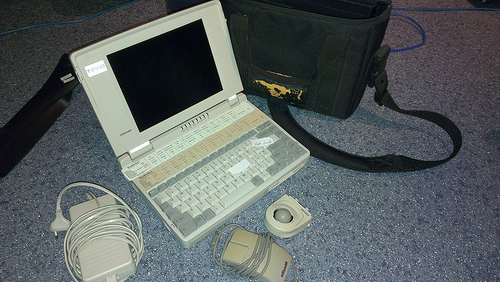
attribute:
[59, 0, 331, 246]
laptop — gray, opened, old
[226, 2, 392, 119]
bag — nylon, black, worn, cloth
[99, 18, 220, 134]
screen — black, blank, dark, empty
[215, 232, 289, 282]
mouse — wrapped, gray, plastic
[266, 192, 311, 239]
trackball — gray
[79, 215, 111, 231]
cord — wrapped, gray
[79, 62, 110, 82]
label — white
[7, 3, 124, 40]
wire — blue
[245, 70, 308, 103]
patch — worn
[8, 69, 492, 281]
floor — empty, blue, gray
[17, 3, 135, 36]
cord — blue